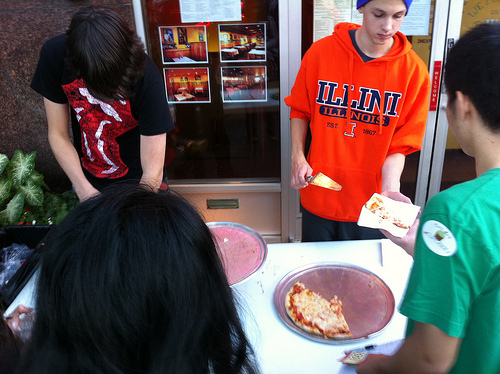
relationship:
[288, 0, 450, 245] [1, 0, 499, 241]
door on building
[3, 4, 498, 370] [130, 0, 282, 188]
building has window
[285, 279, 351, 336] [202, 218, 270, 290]
pizza on platter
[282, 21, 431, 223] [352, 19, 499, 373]
hoodie on boy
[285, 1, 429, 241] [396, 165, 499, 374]
boy wearing green t-shirt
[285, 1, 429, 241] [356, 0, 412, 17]
boy has hat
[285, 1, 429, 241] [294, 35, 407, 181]
boy wearing hoodie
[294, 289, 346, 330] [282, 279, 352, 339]
yellow cheese on pizza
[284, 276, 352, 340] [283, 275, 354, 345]
sauce on pizza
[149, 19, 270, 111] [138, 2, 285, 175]
pictures on window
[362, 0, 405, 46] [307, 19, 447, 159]
head of boy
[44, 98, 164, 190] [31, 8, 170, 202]
arms of boy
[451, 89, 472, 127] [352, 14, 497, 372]
ear of boy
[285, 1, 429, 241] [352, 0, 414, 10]
boy wearing hat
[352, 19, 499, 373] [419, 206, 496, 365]
boy wearing green t-shirt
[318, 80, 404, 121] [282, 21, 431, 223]
letters on hoodie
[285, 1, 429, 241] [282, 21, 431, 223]
boy wearing hoodie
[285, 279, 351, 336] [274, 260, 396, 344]
pizza on pan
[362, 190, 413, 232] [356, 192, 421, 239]
pizza in napkin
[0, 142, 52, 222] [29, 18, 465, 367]
plant in front of building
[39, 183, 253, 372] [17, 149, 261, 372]
head of woman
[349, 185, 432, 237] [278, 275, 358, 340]
piece of pizza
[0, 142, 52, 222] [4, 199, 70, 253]
plant in pot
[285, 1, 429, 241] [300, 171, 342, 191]
boy holding spatula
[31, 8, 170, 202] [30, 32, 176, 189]
boy has black shirt